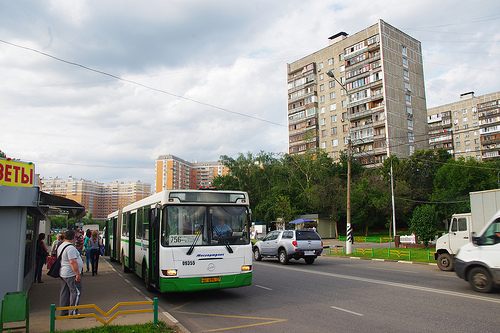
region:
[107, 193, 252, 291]
a white and green bus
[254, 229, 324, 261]
a gray car on the stret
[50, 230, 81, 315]
a man standing on the sidewalk holding a bag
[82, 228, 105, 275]
two women walking on a sidewalk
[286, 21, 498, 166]
tall apartment buildings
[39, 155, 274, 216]
orange and white apartment buildings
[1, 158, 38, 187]
a yellow and red sign above a store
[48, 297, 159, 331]
a small green and yellow fence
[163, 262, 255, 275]
yellow headlights of a bus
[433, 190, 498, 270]
a white truck driving on the street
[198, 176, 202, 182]
part of a building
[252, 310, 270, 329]
part f a line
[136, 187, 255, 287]
this is a bus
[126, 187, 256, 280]
the bus is long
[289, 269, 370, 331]
this is the road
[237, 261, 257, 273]
the light is on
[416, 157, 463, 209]
these are the trees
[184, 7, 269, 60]
this is the sky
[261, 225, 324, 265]
this is a car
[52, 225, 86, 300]
this is a man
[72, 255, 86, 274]
the belly is fat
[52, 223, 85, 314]
this is a person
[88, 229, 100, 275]
this is a person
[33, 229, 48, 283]
this is a person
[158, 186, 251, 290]
this is a bus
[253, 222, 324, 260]
this is a car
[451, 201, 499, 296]
this is a vehicle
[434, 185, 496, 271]
this is a truck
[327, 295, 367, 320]
this is a line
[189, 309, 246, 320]
this is a line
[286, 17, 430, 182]
A building in a city.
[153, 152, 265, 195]
A building in a city.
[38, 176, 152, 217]
A building in a city.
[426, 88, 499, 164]
A building in a city.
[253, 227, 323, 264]
A car on a street.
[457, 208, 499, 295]
A car on a street.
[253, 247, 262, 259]
A tire on a vehicle.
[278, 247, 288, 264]
A tire on a vehicle.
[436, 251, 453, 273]
A tire on a vehicle.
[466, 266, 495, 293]
A tire on a vehicle.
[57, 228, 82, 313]
person standing on the sidewalk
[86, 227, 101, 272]
person standing on the sidewalk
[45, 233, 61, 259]
person standing on the sidewalk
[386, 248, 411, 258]
green and yellow fence section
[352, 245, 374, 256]
green and yellow fence section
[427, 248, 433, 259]
green and yellow fence section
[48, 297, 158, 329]
green and yellow fence section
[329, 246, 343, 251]
green and yellow fence section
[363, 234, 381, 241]
green and yellow fence section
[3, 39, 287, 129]
power line